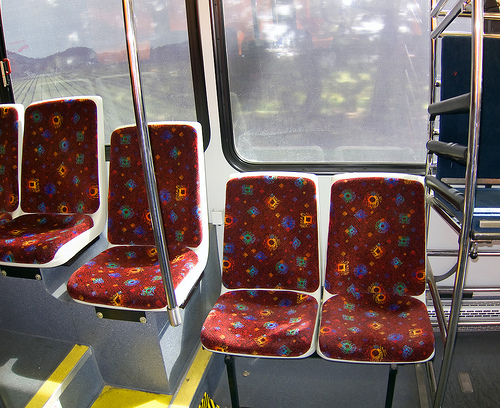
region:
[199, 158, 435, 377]
two deep red bus seats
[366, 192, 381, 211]
yellow design on the seat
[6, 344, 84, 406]
thick yellow line painted on the floor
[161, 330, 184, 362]
light streaming in the bus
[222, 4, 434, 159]
large window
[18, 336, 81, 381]
shadow on the floor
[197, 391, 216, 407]
black and yellow stripes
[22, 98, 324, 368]
three seats, with each seat on the left slightly elevated from the one on the right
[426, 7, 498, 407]
tall, shiny metal pole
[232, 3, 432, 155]
trees speeding out the bus window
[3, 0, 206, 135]
Rear window on the left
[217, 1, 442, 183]
rear window in the center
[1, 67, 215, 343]
Elevated seats on the left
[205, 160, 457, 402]
Two seats in the center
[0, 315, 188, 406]
Steps up to the seats on the left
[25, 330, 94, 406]
Yellow caution tape on stairs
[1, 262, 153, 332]
Metal plate and bolts that hold the seats down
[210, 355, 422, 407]
Legs on the seats in the center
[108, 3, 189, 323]
Metal pole between higher and lower seats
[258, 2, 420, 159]
Trees outside the back of the bus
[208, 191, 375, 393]
the seat is colorful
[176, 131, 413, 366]
the seat is colorful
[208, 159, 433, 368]
double seast on train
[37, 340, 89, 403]
yellow strip on top step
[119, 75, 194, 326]
metal pole on corner of seat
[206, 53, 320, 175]
window with black frame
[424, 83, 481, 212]
three horizontal metal poles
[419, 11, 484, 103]
two vertical metal poles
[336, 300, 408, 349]
print on seat cushion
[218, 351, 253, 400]
black pole under seat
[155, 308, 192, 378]
light reflection under seat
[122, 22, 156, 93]
light reflection on pole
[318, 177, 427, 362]
brown multicolored seats on a bus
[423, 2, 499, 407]
a luggage rack on a bus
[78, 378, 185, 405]
a step painted yellow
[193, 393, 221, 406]
a yellow and black caution sticker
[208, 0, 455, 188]
a back window on a bus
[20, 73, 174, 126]
a field outside a window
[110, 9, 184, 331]
a metal pole on a bus seat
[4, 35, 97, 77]
a mountain outside the window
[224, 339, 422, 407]
grey bus floor under two seats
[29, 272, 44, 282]
a bolt attaching a seat to a bus